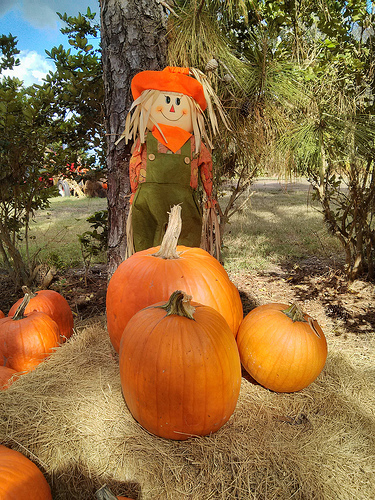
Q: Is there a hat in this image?
A: Yes, there is a hat.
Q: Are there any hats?
A: Yes, there is a hat.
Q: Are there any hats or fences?
A: Yes, there is a hat.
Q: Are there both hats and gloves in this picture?
A: No, there is a hat but no gloves.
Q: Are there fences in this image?
A: No, there are no fences.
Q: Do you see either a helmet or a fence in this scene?
A: No, there are no fences or helmets.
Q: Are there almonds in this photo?
A: No, there are no almonds.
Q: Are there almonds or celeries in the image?
A: No, there are no almonds or celeries.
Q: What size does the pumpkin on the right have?
A: The pumpkin has small size.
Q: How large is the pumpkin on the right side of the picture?
A: The pumpkin is small.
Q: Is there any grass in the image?
A: Yes, there is grass.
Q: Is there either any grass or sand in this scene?
A: Yes, there is grass.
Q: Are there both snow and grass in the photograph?
A: No, there is grass but no snow.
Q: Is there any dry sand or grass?
A: Yes, there is dry grass.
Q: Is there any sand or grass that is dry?
A: Yes, the grass is dry.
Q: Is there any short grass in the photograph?
A: Yes, there is short grass.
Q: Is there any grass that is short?
A: Yes, there is grass that is short.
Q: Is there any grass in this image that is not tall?
A: Yes, there is short grass.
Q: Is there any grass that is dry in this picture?
A: Yes, there is dry grass.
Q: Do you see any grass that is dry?
A: Yes, there is grass that is dry.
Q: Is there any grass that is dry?
A: Yes, there is grass that is dry.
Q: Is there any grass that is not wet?
A: Yes, there is dry grass.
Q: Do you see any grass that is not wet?
A: Yes, there is dry grass.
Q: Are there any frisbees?
A: No, there are no frisbees.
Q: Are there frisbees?
A: No, there are no frisbees.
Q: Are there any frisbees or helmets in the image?
A: No, there are no frisbees or helmets.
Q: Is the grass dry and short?
A: Yes, the grass is dry and short.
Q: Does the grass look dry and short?
A: Yes, the grass is dry and short.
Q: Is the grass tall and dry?
A: No, the grass is dry but short.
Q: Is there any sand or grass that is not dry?
A: No, there is grass but it is dry.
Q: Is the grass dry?
A: Yes, the grass is dry.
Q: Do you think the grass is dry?
A: Yes, the grass is dry.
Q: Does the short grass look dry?
A: Yes, the grass is dry.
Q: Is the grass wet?
A: No, the grass is dry.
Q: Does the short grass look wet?
A: No, the grass is dry.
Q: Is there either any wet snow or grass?
A: No, there is grass but it is dry.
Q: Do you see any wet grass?
A: No, there is grass but it is dry.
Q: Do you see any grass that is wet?
A: No, there is grass but it is dry.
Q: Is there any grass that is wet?
A: No, there is grass but it is dry.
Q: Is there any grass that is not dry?
A: No, there is grass but it is dry.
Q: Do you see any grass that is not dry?
A: No, there is grass but it is dry.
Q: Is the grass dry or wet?
A: The grass is dry.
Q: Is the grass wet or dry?
A: The grass is dry.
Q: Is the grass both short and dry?
A: Yes, the grass is short and dry.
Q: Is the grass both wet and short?
A: No, the grass is short but dry.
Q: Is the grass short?
A: Yes, the grass is short.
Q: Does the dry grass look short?
A: Yes, the grass is short.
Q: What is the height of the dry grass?
A: The grass is short.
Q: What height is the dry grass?
A: The grass is short.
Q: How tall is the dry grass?
A: The grass is short.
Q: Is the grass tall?
A: No, the grass is short.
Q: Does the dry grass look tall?
A: No, the grass is short.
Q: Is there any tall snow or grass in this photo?
A: No, there is grass but it is short.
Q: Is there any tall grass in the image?
A: No, there is grass but it is short.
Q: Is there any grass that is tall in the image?
A: No, there is grass but it is short.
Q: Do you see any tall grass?
A: No, there is grass but it is short.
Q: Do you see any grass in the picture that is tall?
A: No, there is grass but it is short.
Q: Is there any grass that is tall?
A: No, there is grass but it is short.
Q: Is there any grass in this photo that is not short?
A: No, there is grass but it is short.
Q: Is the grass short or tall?
A: The grass is short.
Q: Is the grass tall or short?
A: The grass is short.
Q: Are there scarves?
A: Yes, there is a scarf.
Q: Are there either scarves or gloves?
A: Yes, there is a scarf.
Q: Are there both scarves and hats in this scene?
A: Yes, there are both a scarf and a hat.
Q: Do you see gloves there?
A: No, there are no gloves.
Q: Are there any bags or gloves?
A: No, there are no gloves or bags.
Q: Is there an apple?
A: No, there are no apples.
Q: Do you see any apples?
A: No, there are no apples.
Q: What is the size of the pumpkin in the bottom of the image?
A: The pumpkin is small.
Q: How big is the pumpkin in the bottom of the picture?
A: The pumpkin is small.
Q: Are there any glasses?
A: No, there are no glasses.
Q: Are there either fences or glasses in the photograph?
A: No, there are no glasses or fences.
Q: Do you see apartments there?
A: No, there are no apartments.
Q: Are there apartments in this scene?
A: No, there are no apartments.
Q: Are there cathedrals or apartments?
A: No, there are no apartments or cathedrals.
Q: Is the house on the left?
A: Yes, the house is on the left of the image.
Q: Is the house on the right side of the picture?
A: No, the house is on the left of the image.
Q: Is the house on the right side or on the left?
A: The house is on the left of the image.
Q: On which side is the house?
A: The house is on the left of the image.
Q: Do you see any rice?
A: No, there is no rice.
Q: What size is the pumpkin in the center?
A: The pumpkin is large.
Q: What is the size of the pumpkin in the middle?
A: The pumpkin is large.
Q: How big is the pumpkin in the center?
A: The pumpkin is large.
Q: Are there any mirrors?
A: No, there are no mirrors.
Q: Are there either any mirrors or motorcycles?
A: No, there are no mirrors or motorcycles.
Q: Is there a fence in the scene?
A: No, there are no fences.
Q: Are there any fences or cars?
A: No, there are no fences or cars.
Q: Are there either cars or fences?
A: No, there are no fences or cars.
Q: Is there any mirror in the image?
A: No, there are no mirrors.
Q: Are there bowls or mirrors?
A: No, there are no mirrors or bowls.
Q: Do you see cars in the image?
A: No, there are no cars.